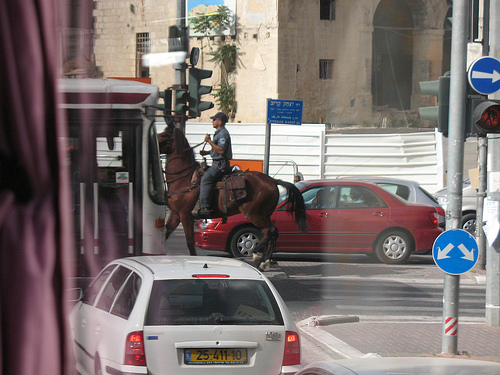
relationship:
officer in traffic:
[193, 111, 233, 216] [51, 148, 478, 372]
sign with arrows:
[434, 228, 480, 271] [440, 242, 476, 262]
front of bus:
[146, 77, 168, 269] [21, 85, 165, 265]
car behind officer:
[226, 185, 438, 268] [193, 111, 233, 216]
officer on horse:
[193, 111, 233, 216] [167, 155, 268, 239]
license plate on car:
[176, 349, 256, 367] [106, 269, 285, 373]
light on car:
[277, 331, 310, 372] [106, 269, 285, 373]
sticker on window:
[103, 162, 134, 183] [93, 127, 133, 265]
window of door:
[93, 127, 133, 265] [71, 124, 130, 275]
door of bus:
[71, 124, 130, 275] [21, 85, 165, 265]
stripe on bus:
[33, 87, 161, 110] [21, 85, 165, 265]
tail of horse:
[271, 172, 316, 242] [167, 155, 268, 239]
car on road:
[226, 185, 438, 268] [243, 262, 489, 329]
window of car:
[154, 287, 262, 315] [106, 269, 285, 373]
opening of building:
[365, 0, 413, 101] [100, 4, 460, 114]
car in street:
[226, 185, 438, 268] [261, 240, 471, 336]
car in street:
[106, 269, 285, 373] [261, 240, 471, 336]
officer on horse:
[212, 109, 230, 171] [167, 155, 268, 239]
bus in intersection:
[21, 85, 165, 265] [38, 13, 493, 360]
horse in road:
[167, 155, 268, 239] [243, 262, 489, 329]